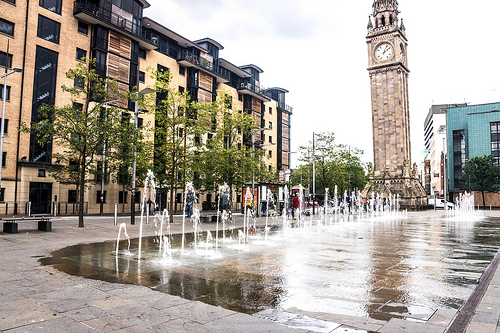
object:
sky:
[141, 0, 500, 174]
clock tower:
[357, 0, 430, 210]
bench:
[0, 216, 54, 235]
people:
[287, 191, 302, 218]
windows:
[0, 50, 13, 71]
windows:
[0, 0, 17, 6]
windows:
[0, 18, 16, 39]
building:
[445, 101, 500, 208]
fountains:
[113, 167, 409, 255]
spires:
[383, 12, 389, 24]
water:
[38, 214, 500, 314]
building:
[422, 98, 468, 200]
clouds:
[141, 0, 500, 180]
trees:
[290, 130, 371, 203]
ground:
[0, 208, 500, 332]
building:
[0, 0, 293, 220]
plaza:
[0, 0, 499, 332]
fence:
[0, 201, 90, 217]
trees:
[10, 54, 143, 227]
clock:
[370, 40, 395, 63]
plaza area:
[0, 0, 500, 332]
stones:
[160, 300, 241, 324]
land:
[0, 208, 500, 331]